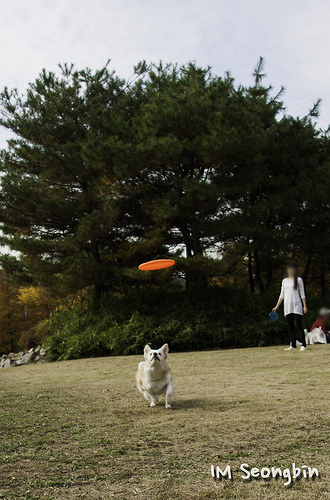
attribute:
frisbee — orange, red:
[134, 254, 181, 273]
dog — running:
[138, 334, 173, 412]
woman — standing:
[267, 261, 310, 350]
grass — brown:
[6, 389, 60, 452]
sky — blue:
[229, 11, 285, 44]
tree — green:
[17, 85, 123, 292]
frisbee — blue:
[269, 312, 282, 323]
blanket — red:
[310, 319, 325, 329]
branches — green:
[299, 96, 325, 123]